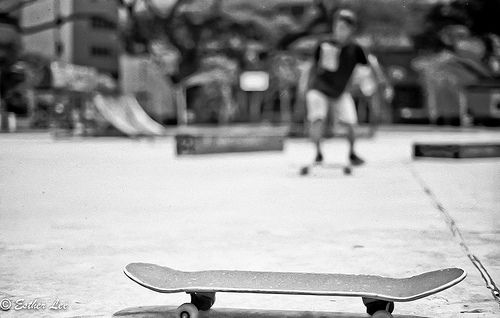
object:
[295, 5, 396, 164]
boy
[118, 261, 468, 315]
skateboard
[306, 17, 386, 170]
man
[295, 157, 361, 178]
skateboard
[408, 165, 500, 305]
lines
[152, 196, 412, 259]
ground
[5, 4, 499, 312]
photo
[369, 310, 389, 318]
wheel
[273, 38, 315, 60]
arm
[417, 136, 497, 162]
ramp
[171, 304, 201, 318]
wheel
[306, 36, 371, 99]
shirt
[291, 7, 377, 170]
skateboarder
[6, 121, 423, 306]
street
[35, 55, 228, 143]
ramp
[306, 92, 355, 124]
shorts